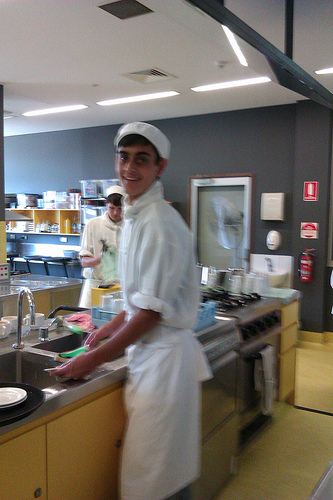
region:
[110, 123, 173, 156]
White cap on man's head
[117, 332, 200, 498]
White apron around man's waist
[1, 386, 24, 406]
Small white plates stacked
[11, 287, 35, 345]
Tall curved sink faucet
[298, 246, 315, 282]
Red fire extinguisher on wall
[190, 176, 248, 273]
Door set into wall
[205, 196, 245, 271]
Silver metal electric fan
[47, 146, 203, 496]
Man washing dishes at sink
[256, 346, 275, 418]
Towel hanging on oven door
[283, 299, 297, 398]
Yellow drawers near oven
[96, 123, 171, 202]
head of a person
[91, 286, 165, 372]
arm of a person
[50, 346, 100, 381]
hand of a person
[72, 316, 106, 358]
hand of a person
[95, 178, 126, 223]
head of a person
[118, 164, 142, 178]
nose of a person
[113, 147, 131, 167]
eye of a person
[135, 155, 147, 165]
eye of a person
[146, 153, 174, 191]
ear of a person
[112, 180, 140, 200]
jaw of a person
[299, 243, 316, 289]
red extinguisher on wall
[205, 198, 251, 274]
fan in the kitchen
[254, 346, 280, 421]
towel hanging from stove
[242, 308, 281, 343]
black knobs on stove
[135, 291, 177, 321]
cuffed sleeve on man's shirt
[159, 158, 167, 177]
the man's left ear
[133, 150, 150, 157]
the man's left eyebrow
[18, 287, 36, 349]
silver faucet on the sink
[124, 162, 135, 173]
the nose on the guy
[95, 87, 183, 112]
light on the ceiling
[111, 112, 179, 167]
white hat on head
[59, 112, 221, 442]
two boys working in kitchen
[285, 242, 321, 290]
fire extinguisher on the wall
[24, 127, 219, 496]
a boy washing dishes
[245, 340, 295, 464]
a towel on the oven door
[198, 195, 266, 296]
a silver standing fan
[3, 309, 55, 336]
three white coffee mugs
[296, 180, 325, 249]
two red and white signs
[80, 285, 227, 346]
a blue drying rack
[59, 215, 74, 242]
a bottle of mustard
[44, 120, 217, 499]
Man holding a sponge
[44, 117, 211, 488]
A man washing dishes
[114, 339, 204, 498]
A white apron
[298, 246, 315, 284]
A red fire extinguisher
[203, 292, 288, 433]
A stainless steel stove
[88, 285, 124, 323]
Part of a rack of dishes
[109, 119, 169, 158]
A white hat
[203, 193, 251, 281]
A silver oscillating fan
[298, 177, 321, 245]
Signs on the wall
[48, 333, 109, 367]
A green dish sponge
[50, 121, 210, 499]
a young man washing dishes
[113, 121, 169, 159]
the hat is white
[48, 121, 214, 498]
the boy is wearing a hat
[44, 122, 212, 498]
the boy is washing dishes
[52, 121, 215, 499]
the boy is wearing an apron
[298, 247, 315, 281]
the fire extinguisher is red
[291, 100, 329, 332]
the fire extinguisher is hanging on the small wall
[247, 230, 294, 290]
the soap dispenser above the sink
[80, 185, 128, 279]
the boy is wearing a hat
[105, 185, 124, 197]
the hat is white